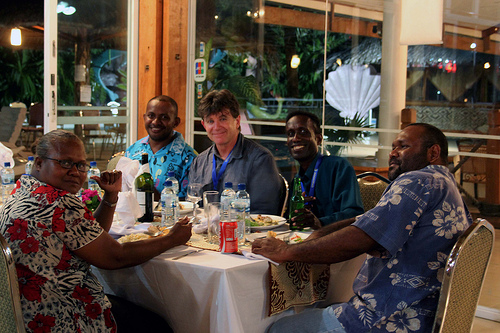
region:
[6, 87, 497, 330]
Five people sitting around a table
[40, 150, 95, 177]
A pair of eyeglasses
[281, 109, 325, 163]
The man is smiling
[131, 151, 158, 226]
Green bottle with white label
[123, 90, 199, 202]
Man wearing a blue shirt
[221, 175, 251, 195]
Two blue caps on bottles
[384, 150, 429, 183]
Facial hair on man's face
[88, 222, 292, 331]
White tablecloth on the table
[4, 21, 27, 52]
A light is turned on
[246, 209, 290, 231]
Food on a plate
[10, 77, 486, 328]
group of people sitting at the table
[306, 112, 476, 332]
man wearing blue shirt with white flowers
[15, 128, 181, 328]
woman sitting at the table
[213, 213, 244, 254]
red can on the table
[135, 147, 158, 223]
green glass bottle on the table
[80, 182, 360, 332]
white tablecloth on the table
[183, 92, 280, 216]
man wearing gray shirt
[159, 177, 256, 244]
water bottles with blue caps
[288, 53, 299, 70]
light reflected on the window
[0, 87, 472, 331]
Five people having a meal at a restaurant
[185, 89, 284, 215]
Older white male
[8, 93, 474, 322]
Four black adults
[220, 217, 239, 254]
Red can of Coca-Cola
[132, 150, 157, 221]
Green bottle of champagne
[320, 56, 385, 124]
White seashell decor on a window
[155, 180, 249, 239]
Three bottles of water on a table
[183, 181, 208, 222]
A wine glass on a table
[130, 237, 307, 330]
White linen tablecloth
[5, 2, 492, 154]
Wall to wall windows in a restaurant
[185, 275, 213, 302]
TABLE CLOTH IS WHITE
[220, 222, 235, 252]
COKE CAN ON THE TABLE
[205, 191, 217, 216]
GLASS ON THE TABLE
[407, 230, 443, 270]
MAN IS WEARING A WHITE AND BLUE SHIRT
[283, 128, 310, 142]
MAN IS WEARING EYE GLASSES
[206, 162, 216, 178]
MAN HAS ON A BLUE KEY CHANGE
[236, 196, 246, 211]
WATER BOTTLES ON THE TABLE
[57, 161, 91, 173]
WOMAN IS WEARING EYE GLASSES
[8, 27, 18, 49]
LIGHT IS ON IN THE CEILING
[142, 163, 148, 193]
WINE BOTTLE IN THE MIDDLE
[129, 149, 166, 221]
GREEN WINE BOTTLE IS ON THE TABLE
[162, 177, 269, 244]
WATER BOTTLES ARE ON THE TABLE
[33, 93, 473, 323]
FIVE PEOPLE ARE SITTING AROUND THE TABLE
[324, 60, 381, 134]
SHELL SCULPTURE IS IN THE BACKGROUND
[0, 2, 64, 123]
SLIDING DOOR IS IN THE OPEN POSITION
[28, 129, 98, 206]
WOMAN IS WEARING GLASSES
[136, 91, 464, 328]
MENS SHIRTS ARE BLUE IN COLOR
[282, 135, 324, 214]
MAN IS HOLDING A BOTTLE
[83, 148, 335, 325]
TABLECLOTH IS WHITE IN COLOR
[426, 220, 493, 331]
CHAIR BACK IS TAN AND SILVER